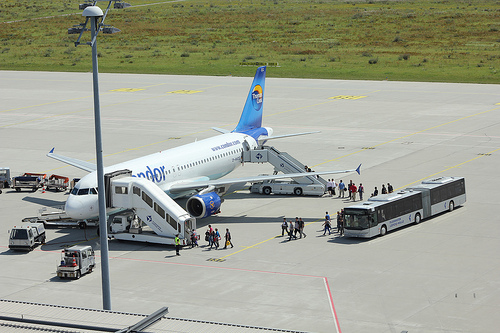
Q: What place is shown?
A: It is a runway.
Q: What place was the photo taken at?
A: It was taken at the runway.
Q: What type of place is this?
A: It is a runway.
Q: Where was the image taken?
A: It was taken at the runway.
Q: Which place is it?
A: It is a runway.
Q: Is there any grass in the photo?
A: Yes, there is grass.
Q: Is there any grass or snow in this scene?
A: Yes, there is grass.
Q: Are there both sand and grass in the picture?
A: No, there is grass but no sand.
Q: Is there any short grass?
A: Yes, there is short grass.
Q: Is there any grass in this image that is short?
A: Yes, there is grass that is short.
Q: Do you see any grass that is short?
A: Yes, there is grass that is short.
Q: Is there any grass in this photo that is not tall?
A: Yes, there is short grass.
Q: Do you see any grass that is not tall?
A: Yes, there is short grass.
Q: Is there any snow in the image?
A: No, there is no snow.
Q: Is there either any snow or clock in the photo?
A: No, there are no snow or clocks.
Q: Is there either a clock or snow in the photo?
A: No, there are no snow or clocks.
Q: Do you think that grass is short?
A: Yes, the grass is short.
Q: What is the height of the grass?
A: The grass is short.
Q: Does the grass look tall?
A: No, the grass is short.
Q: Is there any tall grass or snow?
A: No, there is grass but it is short.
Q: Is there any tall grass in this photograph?
A: No, there is grass but it is short.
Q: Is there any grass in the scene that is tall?
A: No, there is grass but it is short.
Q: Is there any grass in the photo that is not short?
A: No, there is grass but it is short.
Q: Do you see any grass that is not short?
A: No, there is grass but it is short.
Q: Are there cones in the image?
A: No, there are no cones.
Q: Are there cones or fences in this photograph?
A: No, there are no cones or fences.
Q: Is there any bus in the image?
A: Yes, there is a bus.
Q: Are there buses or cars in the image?
A: Yes, there is a bus.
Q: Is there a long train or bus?
A: Yes, there is a long bus.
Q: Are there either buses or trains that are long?
A: Yes, the bus is long.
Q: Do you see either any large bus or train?
A: Yes, there is a large bus.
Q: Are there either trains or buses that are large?
A: Yes, the bus is large.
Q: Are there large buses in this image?
A: Yes, there is a large bus.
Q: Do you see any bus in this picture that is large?
A: Yes, there is a bus that is large.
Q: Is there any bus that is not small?
A: Yes, there is a large bus.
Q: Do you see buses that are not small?
A: Yes, there is a large bus.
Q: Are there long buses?
A: Yes, there is a long bus.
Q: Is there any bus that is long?
A: Yes, there is a bus that is long.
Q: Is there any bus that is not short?
A: Yes, there is a long bus.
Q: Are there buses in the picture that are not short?
A: Yes, there is a long bus.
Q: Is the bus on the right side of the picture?
A: Yes, the bus is on the right of the image.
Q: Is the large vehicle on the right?
A: Yes, the bus is on the right of the image.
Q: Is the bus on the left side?
A: No, the bus is on the right of the image.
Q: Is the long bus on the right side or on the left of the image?
A: The bus is on the right of the image.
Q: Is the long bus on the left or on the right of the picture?
A: The bus is on the right of the image.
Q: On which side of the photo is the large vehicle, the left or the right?
A: The bus is on the right of the image.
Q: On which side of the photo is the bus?
A: The bus is on the right of the image.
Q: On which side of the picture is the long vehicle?
A: The bus is on the right of the image.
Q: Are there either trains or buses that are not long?
A: No, there is a bus but it is long.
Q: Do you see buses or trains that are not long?
A: No, there is a bus but it is long.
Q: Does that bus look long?
A: Yes, the bus is long.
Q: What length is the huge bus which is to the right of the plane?
A: The bus is long.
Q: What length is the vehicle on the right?
A: The bus is long.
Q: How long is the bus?
A: The bus is long.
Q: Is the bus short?
A: No, the bus is long.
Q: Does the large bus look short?
A: No, the bus is long.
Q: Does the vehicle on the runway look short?
A: No, the bus is long.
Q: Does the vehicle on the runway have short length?
A: No, the bus is long.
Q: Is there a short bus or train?
A: No, there is a bus but it is long.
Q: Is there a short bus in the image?
A: No, there is a bus but it is long.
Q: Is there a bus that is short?
A: No, there is a bus but it is long.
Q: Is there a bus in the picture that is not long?
A: No, there is a bus but it is long.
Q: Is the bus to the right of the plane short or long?
A: The bus is long.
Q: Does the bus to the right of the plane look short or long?
A: The bus is long.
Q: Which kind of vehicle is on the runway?
A: The vehicle is a bus.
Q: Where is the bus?
A: The bus is on the runway.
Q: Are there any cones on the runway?
A: No, there is a bus on the runway.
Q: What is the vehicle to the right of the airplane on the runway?
A: The vehicle is a bus.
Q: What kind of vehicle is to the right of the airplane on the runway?
A: The vehicle is a bus.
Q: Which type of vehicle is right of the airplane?
A: The vehicle is a bus.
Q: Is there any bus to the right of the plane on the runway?
A: Yes, there is a bus to the right of the airplane.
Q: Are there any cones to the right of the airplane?
A: No, there is a bus to the right of the airplane.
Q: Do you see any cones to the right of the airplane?
A: No, there is a bus to the right of the airplane.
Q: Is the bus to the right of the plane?
A: Yes, the bus is to the right of the plane.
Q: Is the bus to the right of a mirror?
A: No, the bus is to the right of the plane.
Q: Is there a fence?
A: No, there are no fences.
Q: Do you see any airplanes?
A: Yes, there is an airplane.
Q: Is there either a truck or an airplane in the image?
A: Yes, there is an airplane.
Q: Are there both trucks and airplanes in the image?
A: Yes, there are both an airplane and a truck.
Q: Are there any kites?
A: No, there are no kites.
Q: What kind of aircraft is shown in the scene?
A: The aircraft is an airplane.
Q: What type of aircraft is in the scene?
A: The aircraft is an airplane.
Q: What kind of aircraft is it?
A: The aircraft is an airplane.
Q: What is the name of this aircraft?
A: This is an airplane.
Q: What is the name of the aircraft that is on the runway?
A: The aircraft is an airplane.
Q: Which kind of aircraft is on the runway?
A: The aircraft is an airplane.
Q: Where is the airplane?
A: The airplane is on the runway.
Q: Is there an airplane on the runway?
A: Yes, there is an airplane on the runway.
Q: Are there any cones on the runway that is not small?
A: No, there is an airplane on the runway.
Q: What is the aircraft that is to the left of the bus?
A: The aircraft is an airplane.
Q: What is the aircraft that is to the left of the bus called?
A: The aircraft is an airplane.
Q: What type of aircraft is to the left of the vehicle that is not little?
A: The aircraft is an airplane.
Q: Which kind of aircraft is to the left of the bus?
A: The aircraft is an airplane.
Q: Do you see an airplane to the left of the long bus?
A: Yes, there is an airplane to the left of the bus.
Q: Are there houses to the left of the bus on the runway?
A: No, there is an airplane to the left of the bus.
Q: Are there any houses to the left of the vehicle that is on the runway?
A: No, there is an airplane to the left of the bus.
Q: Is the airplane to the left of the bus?
A: Yes, the airplane is to the left of the bus.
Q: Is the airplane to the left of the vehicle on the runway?
A: Yes, the airplane is to the left of the bus.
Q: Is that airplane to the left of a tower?
A: No, the airplane is to the left of the bus.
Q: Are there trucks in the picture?
A: Yes, there is a truck.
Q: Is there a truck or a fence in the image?
A: Yes, there is a truck.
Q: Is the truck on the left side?
A: Yes, the truck is on the left of the image.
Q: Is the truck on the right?
A: No, the truck is on the left of the image.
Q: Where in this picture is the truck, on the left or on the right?
A: The truck is on the left of the image.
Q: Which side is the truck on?
A: The truck is on the left of the image.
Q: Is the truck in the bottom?
A: Yes, the truck is in the bottom of the image.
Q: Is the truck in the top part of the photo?
A: No, the truck is in the bottom of the image.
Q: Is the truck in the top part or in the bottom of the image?
A: The truck is in the bottom of the image.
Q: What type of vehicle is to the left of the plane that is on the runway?
A: The vehicle is a truck.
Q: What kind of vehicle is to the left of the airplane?
A: The vehicle is a truck.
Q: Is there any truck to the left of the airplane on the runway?
A: Yes, there is a truck to the left of the airplane.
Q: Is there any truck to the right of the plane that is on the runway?
A: No, the truck is to the left of the plane.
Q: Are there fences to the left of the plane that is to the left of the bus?
A: No, there is a truck to the left of the airplane.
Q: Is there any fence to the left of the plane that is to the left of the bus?
A: No, there is a truck to the left of the airplane.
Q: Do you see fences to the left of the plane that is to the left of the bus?
A: No, there is a truck to the left of the airplane.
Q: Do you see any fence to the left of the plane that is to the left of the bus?
A: No, there is a truck to the left of the airplane.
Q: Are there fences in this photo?
A: No, there are no fences.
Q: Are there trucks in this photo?
A: Yes, there is a truck.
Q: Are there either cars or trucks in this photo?
A: Yes, there is a truck.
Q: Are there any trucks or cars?
A: Yes, there is a truck.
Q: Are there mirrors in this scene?
A: No, there are no mirrors.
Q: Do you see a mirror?
A: No, there are no mirrors.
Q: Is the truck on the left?
A: Yes, the truck is on the left of the image.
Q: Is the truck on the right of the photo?
A: No, the truck is on the left of the image.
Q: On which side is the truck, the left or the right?
A: The truck is on the left of the image.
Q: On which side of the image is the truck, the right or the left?
A: The truck is on the left of the image.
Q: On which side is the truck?
A: The truck is on the left of the image.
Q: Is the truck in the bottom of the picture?
A: Yes, the truck is in the bottom of the image.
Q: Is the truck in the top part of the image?
A: No, the truck is in the bottom of the image.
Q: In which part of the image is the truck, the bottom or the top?
A: The truck is in the bottom of the image.